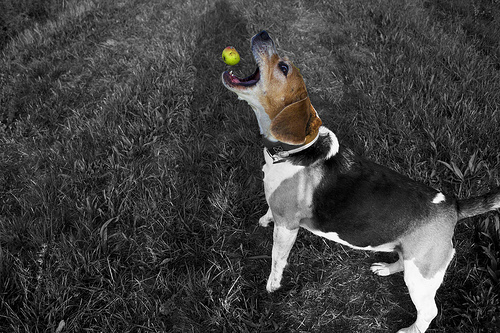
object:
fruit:
[222, 46, 241, 66]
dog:
[220, 30, 499, 333]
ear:
[269, 97, 310, 146]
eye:
[277, 61, 289, 79]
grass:
[0, 0, 500, 333]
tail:
[457, 188, 500, 222]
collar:
[263, 132, 320, 165]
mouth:
[223, 37, 262, 91]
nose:
[254, 30, 273, 42]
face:
[250, 31, 307, 106]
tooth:
[229, 70, 234, 76]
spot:
[431, 191, 447, 204]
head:
[221, 29, 311, 146]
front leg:
[271, 210, 300, 274]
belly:
[299, 196, 402, 252]